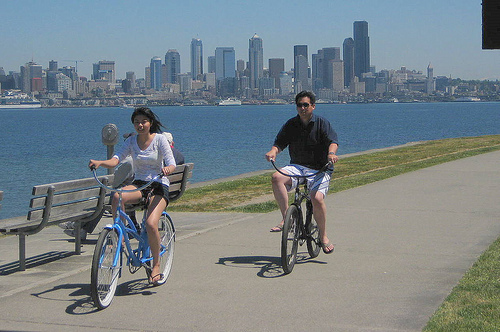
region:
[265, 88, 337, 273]
a man riding a bicycle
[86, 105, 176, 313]
a woman riding a bicycle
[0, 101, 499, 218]
a large body of water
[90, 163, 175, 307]
a blue painted bicycle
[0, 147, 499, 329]
a paved bicycle path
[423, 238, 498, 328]
a patch of green grass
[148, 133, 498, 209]
a patch of green grass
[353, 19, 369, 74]
large building in distance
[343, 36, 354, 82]
large building in distance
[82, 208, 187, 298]
blue bike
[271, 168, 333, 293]
bike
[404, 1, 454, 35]
white clouds in blue sky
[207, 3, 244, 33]
white clouds in blue sky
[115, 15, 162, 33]
white clouds in blue sky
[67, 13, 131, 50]
white clouds in blue sky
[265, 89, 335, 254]
man behind woman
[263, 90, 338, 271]
man is riding a bicycle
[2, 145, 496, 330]
bicycle on top of a paved path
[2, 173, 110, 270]
wooden bench to the left of the woman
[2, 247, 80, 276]
shadow under bench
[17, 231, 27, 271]
metal leg under bench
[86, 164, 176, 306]
blue bicycle under woman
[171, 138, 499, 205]
grass to the left of path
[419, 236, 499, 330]
grass to the right of path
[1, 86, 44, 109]
a boat floating on top of the water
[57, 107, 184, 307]
young woman on blue bike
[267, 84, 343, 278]
man riding bike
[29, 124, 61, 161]
waves in dark blue water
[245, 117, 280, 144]
waves in dark blue water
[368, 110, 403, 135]
waves in dark blue water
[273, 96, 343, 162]
man wearing a black shirt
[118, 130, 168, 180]
woman wearing a white shirt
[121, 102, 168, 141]
woman with black hair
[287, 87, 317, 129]
man with black hair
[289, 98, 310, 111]
man wearing black sunglasses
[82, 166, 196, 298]
woman riding a blue bike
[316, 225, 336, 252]
man wearing slippers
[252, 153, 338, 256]
man riding a black bike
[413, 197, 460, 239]
the sidewalk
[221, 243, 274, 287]
a shadow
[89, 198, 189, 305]
a blue bike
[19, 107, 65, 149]
the ocean water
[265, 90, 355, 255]
man riding a bike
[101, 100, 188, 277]
the women is riding the bike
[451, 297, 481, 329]
the lawn is green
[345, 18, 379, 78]
a tall building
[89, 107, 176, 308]
woman wearing white top riding bicycle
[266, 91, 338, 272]
man wearing black top riding bicycle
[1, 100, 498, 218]
blue body of water filled with ripples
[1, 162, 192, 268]
long wooden plank and metal bench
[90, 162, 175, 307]
old fashioned cornflower blue bicycle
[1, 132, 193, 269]
person with grey hair sitting on long bench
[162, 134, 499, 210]
patch of green grass with bare spots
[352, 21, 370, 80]
tall flat topped black office building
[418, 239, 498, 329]
small lush patch of green grass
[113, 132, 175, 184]
long sleeved scoop necked white shirt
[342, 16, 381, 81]
a building in a city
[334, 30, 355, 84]
a building in a city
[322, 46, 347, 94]
a building in a city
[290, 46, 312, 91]
a building in a city